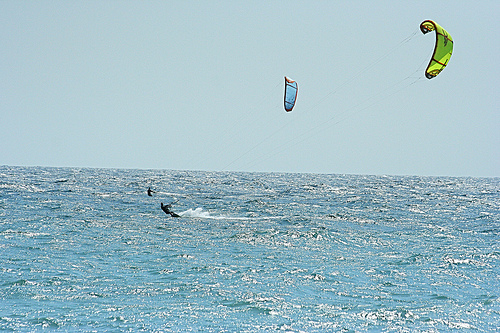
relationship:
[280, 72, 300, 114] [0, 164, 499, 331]
blue kite above water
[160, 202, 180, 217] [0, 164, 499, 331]
man in water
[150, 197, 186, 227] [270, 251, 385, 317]
man in water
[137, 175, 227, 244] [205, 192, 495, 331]
man skating in water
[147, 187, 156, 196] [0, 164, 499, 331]
man in water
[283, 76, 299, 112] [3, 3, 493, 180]
blue kite in sky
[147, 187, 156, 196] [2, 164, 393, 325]
man skiing in water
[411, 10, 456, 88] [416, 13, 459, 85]
kite in sky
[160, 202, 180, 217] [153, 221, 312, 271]
man leaning back on water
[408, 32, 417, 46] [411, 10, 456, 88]
strings of kite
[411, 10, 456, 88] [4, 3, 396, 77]
kite in sky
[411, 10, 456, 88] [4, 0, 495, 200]
kite in sky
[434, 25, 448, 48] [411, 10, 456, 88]
design on kite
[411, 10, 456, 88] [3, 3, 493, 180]
kite in sky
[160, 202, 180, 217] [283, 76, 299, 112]
man holding onto blue kite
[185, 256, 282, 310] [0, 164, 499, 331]
light shining off water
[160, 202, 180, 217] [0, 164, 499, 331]
man parasailing water